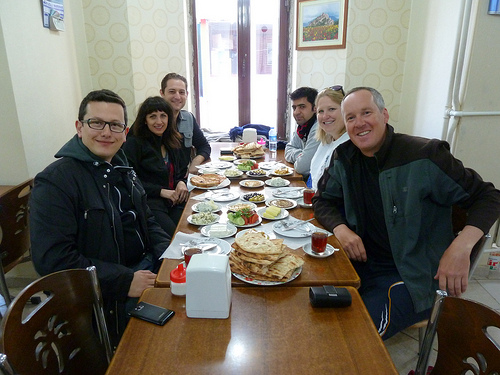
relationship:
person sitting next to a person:
[314, 79, 424, 176] [74, 72, 194, 185]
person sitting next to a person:
[310, 89, 357, 181] [312, 87, 482, 317]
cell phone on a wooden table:
[128, 300, 176, 327] [109, 140, 398, 373]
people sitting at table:
[35, 37, 478, 303] [270, 325, 370, 364]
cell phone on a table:
[128, 300, 176, 327] [109, 140, 398, 373]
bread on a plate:
[224, 222, 309, 280] [230, 259, 307, 288]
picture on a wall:
[293, 3, 352, 54] [356, 18, 404, 60]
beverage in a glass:
[307, 224, 332, 261] [300, 185, 314, 206]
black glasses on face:
[83, 115, 127, 132] [69, 75, 134, 164]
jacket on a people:
[30, 142, 172, 305] [27, 90, 173, 355]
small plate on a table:
[302, 240, 337, 260] [154, 136, 363, 284]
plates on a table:
[166, 146, 330, 261] [169, 274, 419, 362]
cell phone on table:
[118, 282, 185, 331] [103, 126, 406, 368]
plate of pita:
[227, 228, 309, 291] [223, 228, 309, 291]